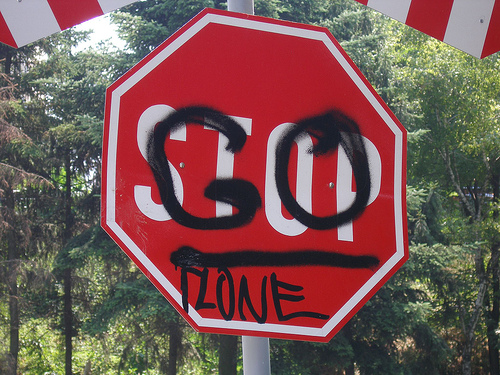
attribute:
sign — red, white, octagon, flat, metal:
[90, 4, 422, 353]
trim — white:
[310, 25, 406, 134]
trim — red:
[201, 11, 330, 47]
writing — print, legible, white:
[146, 104, 377, 322]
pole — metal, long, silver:
[233, 335, 279, 373]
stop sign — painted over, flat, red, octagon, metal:
[98, 5, 410, 342]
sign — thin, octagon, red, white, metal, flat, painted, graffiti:
[100, 6, 407, 342]